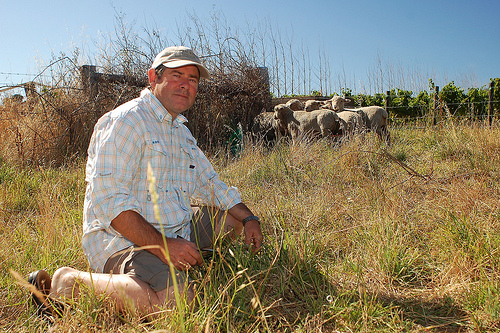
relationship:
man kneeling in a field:
[12, 55, 273, 332] [4, 107, 496, 332]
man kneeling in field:
[12, 55, 273, 332] [4, 107, 496, 332]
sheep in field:
[250, 83, 383, 151] [4, 107, 496, 332]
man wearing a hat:
[12, 55, 273, 332] [147, 42, 208, 72]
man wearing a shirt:
[12, 55, 273, 332] [88, 95, 236, 272]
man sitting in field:
[12, 55, 273, 332] [4, 107, 496, 332]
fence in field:
[0, 63, 499, 114] [4, 107, 496, 332]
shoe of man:
[28, 269, 61, 318] [12, 55, 273, 332]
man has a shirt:
[12, 55, 273, 332] [88, 95, 236, 272]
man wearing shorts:
[12, 55, 273, 332] [108, 200, 222, 293]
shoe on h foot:
[28, 269, 61, 318] [54, 267, 77, 307]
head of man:
[144, 63, 196, 111] [12, 55, 273, 332]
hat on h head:
[147, 42, 208, 72] [144, 63, 196, 111]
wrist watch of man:
[240, 214, 261, 225] [12, 55, 273, 332]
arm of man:
[227, 194, 257, 225] [12, 55, 273, 332]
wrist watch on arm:
[240, 214, 261, 225] [227, 194, 257, 225]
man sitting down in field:
[12, 55, 273, 332] [4, 107, 496, 332]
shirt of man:
[88, 95, 236, 272] [12, 55, 273, 332]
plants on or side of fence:
[282, 85, 499, 129] [0, 63, 499, 114]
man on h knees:
[12, 55, 273, 332] [160, 212, 245, 328]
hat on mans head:
[147, 42, 208, 72] [144, 63, 196, 111]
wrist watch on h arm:
[240, 214, 261, 225] [227, 194, 257, 225]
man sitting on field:
[12, 55, 273, 332] [4, 107, 496, 332]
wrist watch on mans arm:
[240, 214, 261, 225] [227, 194, 257, 225]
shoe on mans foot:
[28, 269, 61, 318] [54, 267, 77, 307]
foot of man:
[54, 267, 77, 307] [12, 55, 273, 332]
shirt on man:
[88, 95, 236, 272] [12, 55, 273, 332]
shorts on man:
[108, 200, 222, 293] [12, 55, 273, 332]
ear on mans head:
[148, 71, 157, 91] [144, 63, 196, 111]